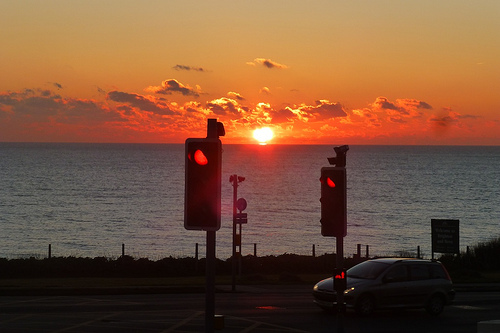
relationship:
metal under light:
[187, 169, 222, 331] [193, 147, 212, 166]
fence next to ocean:
[4, 246, 498, 267] [2, 146, 500, 251]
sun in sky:
[248, 123, 279, 148] [2, 3, 498, 147]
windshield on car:
[341, 257, 393, 281] [313, 255, 457, 317]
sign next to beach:
[431, 219, 460, 255] [0, 257, 496, 285]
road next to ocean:
[0, 291, 496, 332] [2, 146, 500, 251]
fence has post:
[4, 246, 498, 267] [120, 243, 126, 260]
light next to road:
[193, 147, 212, 166] [0, 291, 496, 332]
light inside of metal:
[193, 147, 212, 166] [187, 169, 222, 331]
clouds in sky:
[2, 55, 488, 141] [2, 3, 498, 147]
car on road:
[313, 255, 457, 317] [0, 291, 496, 332]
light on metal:
[193, 147, 212, 166] [187, 169, 222, 331]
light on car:
[311, 284, 319, 293] [313, 255, 457, 317]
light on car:
[193, 147, 212, 166] [313, 255, 457, 317]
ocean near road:
[2, 146, 500, 251] [0, 291, 496, 332]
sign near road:
[431, 219, 460, 255] [0, 291, 496, 332]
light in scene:
[193, 147, 212, 166] [4, 1, 499, 332]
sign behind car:
[431, 219, 460, 255] [313, 255, 457, 317]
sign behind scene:
[431, 219, 460, 255] [4, 1, 499, 332]